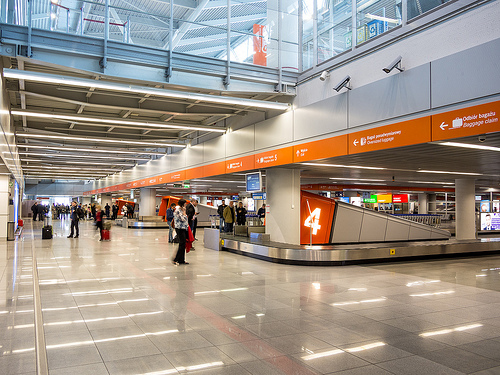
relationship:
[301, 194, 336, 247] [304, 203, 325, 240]
sign says 4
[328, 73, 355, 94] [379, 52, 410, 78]
video camera next to video camera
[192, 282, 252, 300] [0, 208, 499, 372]
light reflection on floor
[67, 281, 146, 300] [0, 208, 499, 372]
light reflection on floor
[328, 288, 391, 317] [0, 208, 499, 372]
light reflection on floor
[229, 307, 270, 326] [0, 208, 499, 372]
light reflection on floor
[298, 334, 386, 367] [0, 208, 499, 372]
light reflection on floor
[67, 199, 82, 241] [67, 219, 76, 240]
person has leg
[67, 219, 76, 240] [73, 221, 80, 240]
leg apart from leg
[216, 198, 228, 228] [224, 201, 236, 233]
man next to man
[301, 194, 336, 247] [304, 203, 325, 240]
sign has 4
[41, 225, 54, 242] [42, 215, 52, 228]
bag has handle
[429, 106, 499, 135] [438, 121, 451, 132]
sign has arrow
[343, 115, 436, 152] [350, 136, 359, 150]
sign has arrow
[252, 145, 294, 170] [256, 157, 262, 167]
sign has arrow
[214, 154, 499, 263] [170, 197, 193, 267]
baggage carousel in front of woman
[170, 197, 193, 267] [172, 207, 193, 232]
woman has top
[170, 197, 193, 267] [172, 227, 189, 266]
woman has pants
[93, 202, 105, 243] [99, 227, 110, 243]
person has bag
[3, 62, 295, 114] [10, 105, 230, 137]
light fixture next to light fixture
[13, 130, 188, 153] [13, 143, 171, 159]
light fixture next to light fixture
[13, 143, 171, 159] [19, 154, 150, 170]
light fixture next to light fixture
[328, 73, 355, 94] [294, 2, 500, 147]
video camera on wall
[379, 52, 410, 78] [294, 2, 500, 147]
video camera on wall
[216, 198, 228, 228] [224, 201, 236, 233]
man standing next to man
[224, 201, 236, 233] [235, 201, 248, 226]
man together with man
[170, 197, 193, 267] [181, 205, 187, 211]
woman talking on phone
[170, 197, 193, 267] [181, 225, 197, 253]
woman has coat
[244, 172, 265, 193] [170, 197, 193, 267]
television screen in front of woman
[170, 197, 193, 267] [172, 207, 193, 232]
woman wears top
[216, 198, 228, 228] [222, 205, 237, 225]
man has jacket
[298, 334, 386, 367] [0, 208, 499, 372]
light reflection shining on floor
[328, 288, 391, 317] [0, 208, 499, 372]
light reflection shining on floor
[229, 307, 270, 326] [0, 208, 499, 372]
light reflection shining on floor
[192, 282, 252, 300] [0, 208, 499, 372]
light reflection shining on floor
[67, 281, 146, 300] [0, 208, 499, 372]
light reflection shining on floor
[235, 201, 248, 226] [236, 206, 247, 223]
man in coat